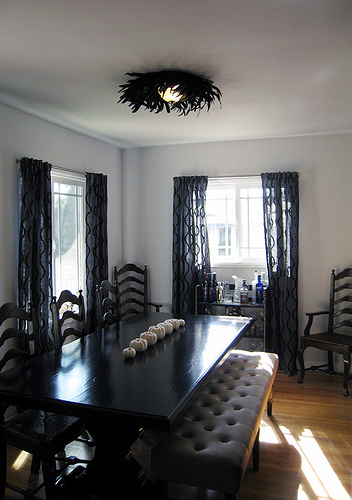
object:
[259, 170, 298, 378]
curtain panel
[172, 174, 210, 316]
curtain panel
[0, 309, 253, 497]
table